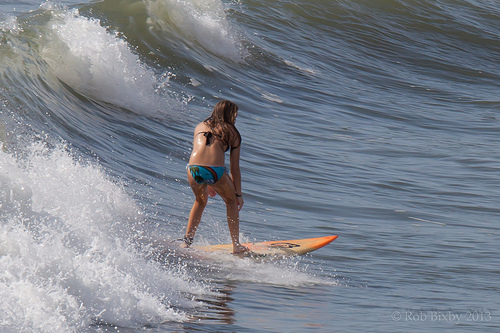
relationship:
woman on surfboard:
[184, 99, 253, 257] [180, 234, 340, 257]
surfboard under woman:
[180, 234, 340, 257] [184, 99, 253, 257]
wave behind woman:
[2, 0, 256, 332] [184, 99, 253, 257]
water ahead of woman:
[2, 1, 498, 332] [184, 99, 253, 257]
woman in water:
[184, 99, 253, 257] [2, 1, 498, 332]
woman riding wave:
[184, 99, 253, 257] [2, 0, 256, 332]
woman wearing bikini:
[184, 99, 253, 257] [189, 131, 230, 182]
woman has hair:
[184, 99, 253, 257] [203, 99, 242, 152]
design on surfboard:
[269, 239, 300, 251] [180, 234, 340, 257]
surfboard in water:
[180, 234, 340, 257] [2, 1, 498, 332]